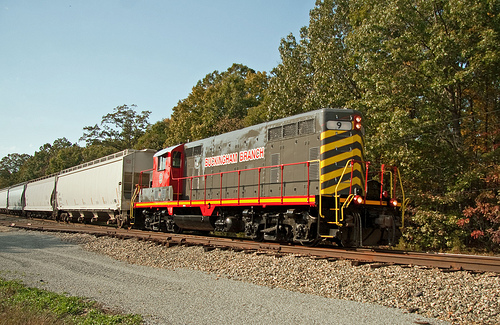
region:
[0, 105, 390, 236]
A train is traveling down the tracks.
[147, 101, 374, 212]
A yellow and black striped rectangle on the locomotive train.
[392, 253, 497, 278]
The rail of the train track.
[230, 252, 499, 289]
The track ballast is gravel next to the tracks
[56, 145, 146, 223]
A white car on the train.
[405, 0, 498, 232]
A tree next to the train.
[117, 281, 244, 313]
Asphalt on the ground.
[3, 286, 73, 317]
The grass is green.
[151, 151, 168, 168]
A window on the train.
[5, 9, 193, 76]
The sky is blue.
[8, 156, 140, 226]
Three gray traincars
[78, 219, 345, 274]
Brown railroad tracks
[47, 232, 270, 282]
Gravel alongside the tracks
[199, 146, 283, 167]
Labeling on a train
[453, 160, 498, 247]
Flowers in the bushes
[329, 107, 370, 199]
Yellow and gray stripes in a v shape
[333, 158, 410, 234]
Multi colored railings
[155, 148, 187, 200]
The red portion of a rail car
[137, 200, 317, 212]
Red and yellow striping alongside a car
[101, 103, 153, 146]
A tall green tree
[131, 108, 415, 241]
locomotive on the front of the train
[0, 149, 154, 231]
white train cars behind the locomotive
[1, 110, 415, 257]
train on the rail road tracks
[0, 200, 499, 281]
rail road tracks running next to the road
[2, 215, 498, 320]
gravel under the rail road tracks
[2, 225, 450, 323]
road running next to the tracks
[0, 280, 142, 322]
patch of grass next to the road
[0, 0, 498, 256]
trees next to the rail road tracks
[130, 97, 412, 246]
red, yellow, and black locomotive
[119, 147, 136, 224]
white ladder on the passenger car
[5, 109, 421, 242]
a train on a track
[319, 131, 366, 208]
black and yellow front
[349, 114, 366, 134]
light on the front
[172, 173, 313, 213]
a red rail on the side of train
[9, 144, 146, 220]
white trankers on track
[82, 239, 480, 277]
rusty rail road tracks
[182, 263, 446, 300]
gravels along the track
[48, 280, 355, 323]
gravel road along tracks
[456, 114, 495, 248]
red tree leaves on a tree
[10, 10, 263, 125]
clear blue sky over train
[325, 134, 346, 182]
black and yellow lines on front of train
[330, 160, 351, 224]
yellow railing on front of train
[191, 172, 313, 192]
red railing along the train car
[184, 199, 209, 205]
yellow stripe on the bottom of railing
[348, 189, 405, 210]
lights are on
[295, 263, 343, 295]
gravel along the tracks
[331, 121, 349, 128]
9 written in black on front of train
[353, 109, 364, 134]
two lights next to the 9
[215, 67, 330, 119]
trees along the tracks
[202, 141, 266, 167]
BUCKINGHAM BRANCH written in red on side of train car